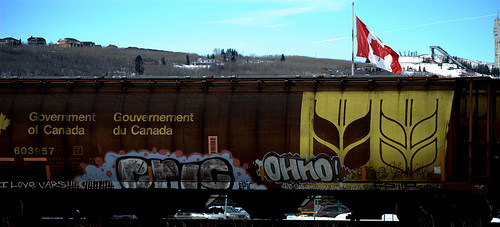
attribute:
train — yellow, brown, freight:
[0, 75, 499, 227]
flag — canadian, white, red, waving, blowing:
[355, 16, 402, 75]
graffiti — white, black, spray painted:
[254, 151, 349, 185]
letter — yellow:
[113, 112, 122, 123]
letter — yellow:
[130, 125, 139, 136]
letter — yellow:
[91, 112, 97, 123]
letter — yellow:
[166, 127, 174, 136]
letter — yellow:
[27, 126, 35, 135]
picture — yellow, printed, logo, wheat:
[299, 89, 455, 190]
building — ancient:
[1, 37, 22, 48]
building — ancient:
[191, 57, 216, 66]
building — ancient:
[56, 37, 96, 48]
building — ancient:
[27, 36, 47, 45]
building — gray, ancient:
[492, 18, 500, 69]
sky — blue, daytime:
[1, 0, 500, 63]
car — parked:
[314, 204, 353, 218]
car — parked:
[210, 205, 247, 220]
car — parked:
[192, 212, 227, 220]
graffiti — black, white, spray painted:
[71, 147, 268, 191]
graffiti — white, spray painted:
[0, 180, 114, 189]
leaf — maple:
[369, 38, 392, 61]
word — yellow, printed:
[113, 111, 195, 123]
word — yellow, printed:
[111, 126, 127, 136]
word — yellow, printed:
[131, 124, 174, 136]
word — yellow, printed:
[27, 125, 40, 136]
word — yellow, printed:
[43, 124, 85, 136]